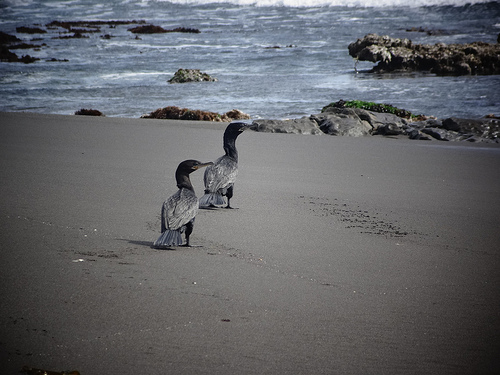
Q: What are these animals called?
A: Birds.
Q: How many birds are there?
A: Two.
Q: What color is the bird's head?
A: Black.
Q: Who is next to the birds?
A: No one.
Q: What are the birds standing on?
A: Sand.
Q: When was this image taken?
A: Daytime.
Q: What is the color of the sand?
A: Brown.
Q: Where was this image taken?
A: On a beach.